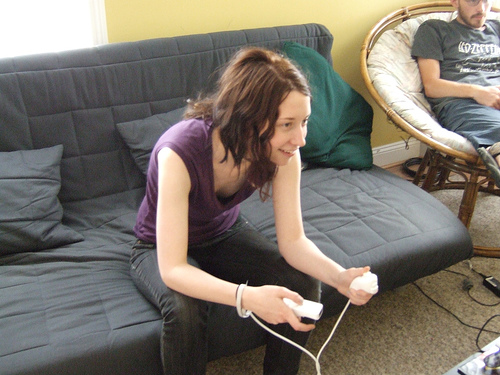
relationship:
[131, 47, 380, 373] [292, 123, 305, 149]
girl has nose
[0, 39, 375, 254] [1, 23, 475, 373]
pillows on couch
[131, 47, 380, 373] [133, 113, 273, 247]
girl wearing shirt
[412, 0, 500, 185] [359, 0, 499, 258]
boy in chair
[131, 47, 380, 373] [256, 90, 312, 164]
girl has face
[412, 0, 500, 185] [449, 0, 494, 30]
boy has face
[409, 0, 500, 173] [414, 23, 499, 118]
boy has arm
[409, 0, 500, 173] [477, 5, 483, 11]
boy has nose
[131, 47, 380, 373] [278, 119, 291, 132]
girl has eye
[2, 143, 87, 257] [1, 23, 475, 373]
pillow on couch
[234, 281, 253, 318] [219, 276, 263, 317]
bracelet on wrist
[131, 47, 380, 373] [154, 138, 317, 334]
girl has arm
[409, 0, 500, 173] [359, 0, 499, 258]
boy in chair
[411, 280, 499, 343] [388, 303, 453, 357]
cables on floor